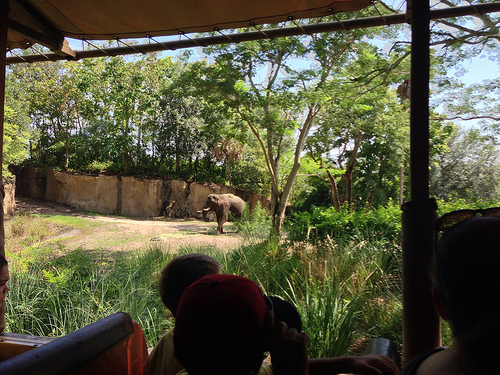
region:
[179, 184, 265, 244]
elephant at zoo exhibit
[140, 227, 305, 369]
children watching elephant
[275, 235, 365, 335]
grasses growing behind fence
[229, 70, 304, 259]
tree growing tall behind fence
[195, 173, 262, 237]
grey elephant behind fence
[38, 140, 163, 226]
stone barrier behind elephant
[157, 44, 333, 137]
blue sky shining through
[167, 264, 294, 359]
red baseball cap on kid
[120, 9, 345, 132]
roof of safari vehicle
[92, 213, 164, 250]
ground with dirt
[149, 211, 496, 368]
Group of individuals watching the exhibit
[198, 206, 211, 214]
Saber tooth of animal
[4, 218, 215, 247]
Open space around the forest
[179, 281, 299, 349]
Red hat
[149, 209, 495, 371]
Group of passengers on a tour ride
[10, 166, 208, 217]
Cement stand holding a group of trees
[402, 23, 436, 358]
Pole arm of the tour ride used for holding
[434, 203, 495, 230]
Sunglasses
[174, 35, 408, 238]
Small tree in front of passengers on the tour ride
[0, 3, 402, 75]
Cross section of the roof on tour ride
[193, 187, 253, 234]
The elephant being looked at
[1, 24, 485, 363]
The elephants enclosure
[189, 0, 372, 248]
Large tree next to the elephant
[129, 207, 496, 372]
The people looking at the elephant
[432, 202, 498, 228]
Sunglasses atop a spectators head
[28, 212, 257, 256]
Dirt patch on the ground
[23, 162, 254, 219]
Dirt wall behind the elephant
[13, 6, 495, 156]
Sky poking through the trees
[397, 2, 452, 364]
Pole in front of the person with sunglasses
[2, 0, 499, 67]
Canopy over the people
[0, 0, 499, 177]
a blue sky in the background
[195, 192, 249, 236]
a gray elephant on the dirt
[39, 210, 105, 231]
a patch of green grass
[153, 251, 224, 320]
the head of a child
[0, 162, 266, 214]
a small cliff face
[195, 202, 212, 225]
the trunk of an elephant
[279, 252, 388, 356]
tall green grass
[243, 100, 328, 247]
a brown tree trunk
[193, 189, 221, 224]
the head of an elephant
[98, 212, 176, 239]
a patch of brown dirt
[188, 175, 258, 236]
Elephant on display.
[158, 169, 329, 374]
People at the zoo watching an elephant.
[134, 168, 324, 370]
People on a safari.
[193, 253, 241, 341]
Boy with a red hat.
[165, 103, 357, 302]
Elephant in an enclosure.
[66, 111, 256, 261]
Elephant walking around.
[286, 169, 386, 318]
Vegetation in the elephant enclosure.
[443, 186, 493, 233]
Sunglasses on the person's head.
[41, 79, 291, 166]
Trees above the elephant.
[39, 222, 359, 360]
People on a vehicle observing the elephant.